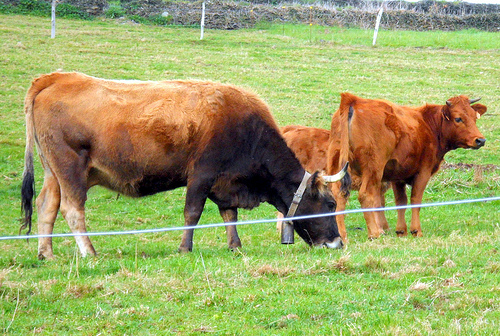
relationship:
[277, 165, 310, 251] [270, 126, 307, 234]
collar around neck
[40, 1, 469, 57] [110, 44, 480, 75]
fence around pasture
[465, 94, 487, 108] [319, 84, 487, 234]
horn on bull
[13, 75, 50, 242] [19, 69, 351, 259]
tail on cow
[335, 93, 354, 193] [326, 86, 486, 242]
tail on cow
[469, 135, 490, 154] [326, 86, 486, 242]
nose on cow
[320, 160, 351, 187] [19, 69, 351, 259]
horn on cow